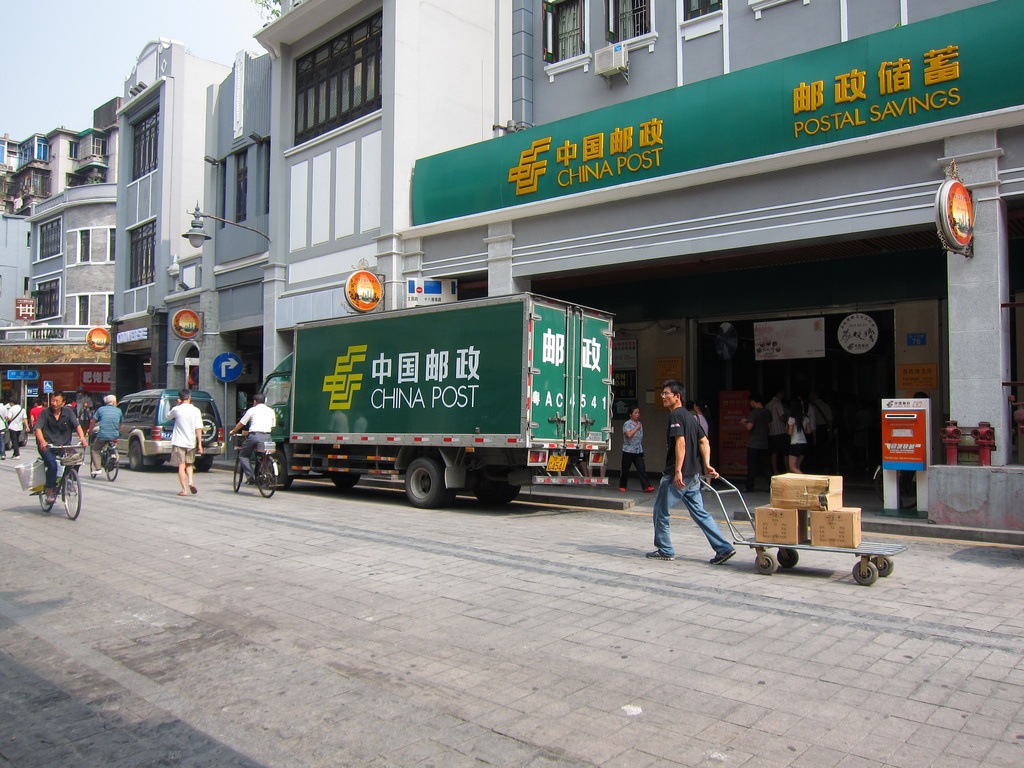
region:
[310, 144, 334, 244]
glass is clean and clear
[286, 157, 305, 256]
glass is clean and clear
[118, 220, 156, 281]
glass is clean and clear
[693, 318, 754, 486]
glass is clean and clear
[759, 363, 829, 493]
glass is clean and clear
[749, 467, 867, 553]
3 boxes stacked on a cart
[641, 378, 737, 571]
Man pulling cart with boxes on it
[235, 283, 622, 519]
Large green delivery truck with white and yellow graphics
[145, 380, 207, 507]
Person walking away with white t-shirt and shorts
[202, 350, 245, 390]
blue and white right-hand turn sign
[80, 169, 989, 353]
4 round signs attached to the buildings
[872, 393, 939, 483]
red, white and blue drop-off box on a black post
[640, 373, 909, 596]
man pulling a roller cart with boxes on it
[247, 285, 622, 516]
green truck parked in front of building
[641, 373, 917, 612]
A man pulling a cart behind him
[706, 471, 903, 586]
A grey metal cart.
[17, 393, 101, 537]
A person riding on a bicycle.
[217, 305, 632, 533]
A large green truck with white and yellow writing on it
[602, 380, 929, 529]
people on the sidewalk.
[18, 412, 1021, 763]
The road.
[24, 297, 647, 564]
Vehicles on the road.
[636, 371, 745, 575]
A man with black hair.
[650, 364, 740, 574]
A man wearing blue jeans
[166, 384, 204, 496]
A person walking on a street.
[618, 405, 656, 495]
A person walking on a sidewalk.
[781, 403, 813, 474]
A person walking on a sidewalk.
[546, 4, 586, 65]
A window on a building.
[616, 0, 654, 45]
A window on a building.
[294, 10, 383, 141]
A window on a building.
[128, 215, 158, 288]
A window on a building.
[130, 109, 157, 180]
A window on a building.